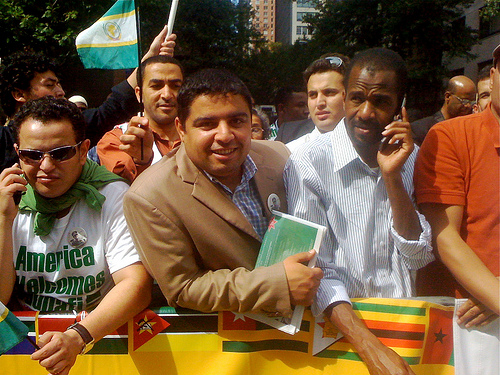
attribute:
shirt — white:
[279, 115, 437, 329]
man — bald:
[405, 73, 478, 145]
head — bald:
[442, 75, 477, 115]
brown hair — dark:
[174, 66, 256, 128]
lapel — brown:
[171, 162, 258, 242]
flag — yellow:
[145, 310, 280, 372]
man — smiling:
[120, 67, 308, 339]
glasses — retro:
[14, 131, 114, 186]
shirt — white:
[12, 164, 154, 362]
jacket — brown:
[144, 165, 226, 252]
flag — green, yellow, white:
[68, 8, 144, 73]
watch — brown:
[74, 321, 94, 353]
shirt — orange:
[410, 99, 497, 261]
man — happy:
[2, 93, 161, 371]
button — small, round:
[264, 189, 283, 215]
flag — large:
[60, 5, 192, 104]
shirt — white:
[284, 122, 420, 297]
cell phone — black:
[379, 94, 444, 171]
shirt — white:
[2, 183, 161, 338]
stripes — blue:
[332, 184, 366, 255]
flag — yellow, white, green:
[71, 0, 145, 73]